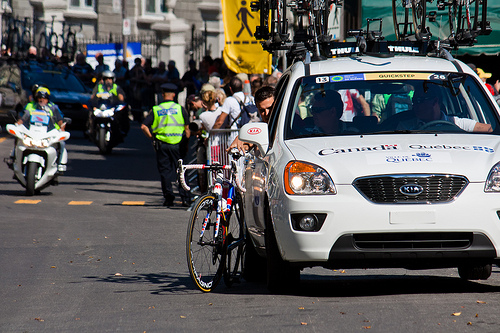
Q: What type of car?
A: Kia.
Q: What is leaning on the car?
A: Bicycle.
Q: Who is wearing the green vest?
A: Policeman.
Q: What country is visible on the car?
A: Canada.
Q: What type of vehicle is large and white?
A: Car.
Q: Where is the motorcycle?
A: On the left.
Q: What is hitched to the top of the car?
A: Bicycles.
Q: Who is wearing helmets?
A: Two motorcyclists.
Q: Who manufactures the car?
A: Kia.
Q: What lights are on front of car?
A: Headlights.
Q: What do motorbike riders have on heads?
A: Helmets.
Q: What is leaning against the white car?
A: Racing bike.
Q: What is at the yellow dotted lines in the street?
A: Man on a white motorcycle.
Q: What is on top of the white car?
A: Bicycle rack.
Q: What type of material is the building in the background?
A: Grey stone.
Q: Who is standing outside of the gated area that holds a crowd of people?
A: Man wearing a yellow fluorescent vest.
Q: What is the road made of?
A: Black asphalt.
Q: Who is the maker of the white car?
A: Kia.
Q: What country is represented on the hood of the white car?
A: Canada.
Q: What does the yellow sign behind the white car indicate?
A: Crosswalk.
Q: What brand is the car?
A: Kia.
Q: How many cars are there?
A: 2.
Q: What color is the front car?
A: White.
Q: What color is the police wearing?
A: Black and yellow.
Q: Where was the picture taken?
A: On the street.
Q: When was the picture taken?
A: In the daytime.